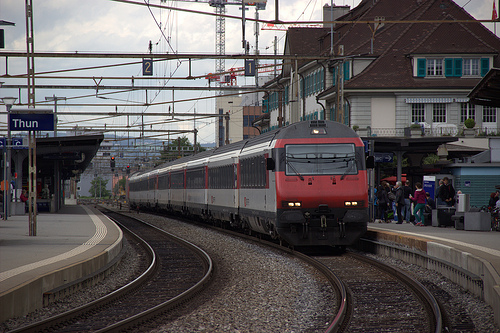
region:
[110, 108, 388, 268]
A train pulling into a station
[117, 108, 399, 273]
A train pulling into a station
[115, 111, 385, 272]
A train pulling into a station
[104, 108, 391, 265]
A train pulling into a station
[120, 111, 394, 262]
A train pulling into a station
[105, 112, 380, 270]
A train pulling into a station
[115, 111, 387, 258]
A train pulling into a station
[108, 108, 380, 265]
A train pulling into a station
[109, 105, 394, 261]
A train pulling into a station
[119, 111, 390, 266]
A train pulling into a station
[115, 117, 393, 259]
A train pulling into a station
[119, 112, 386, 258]
A train pulling into a station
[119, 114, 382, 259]
A train pulling into a station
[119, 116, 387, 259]
A train pulling into a station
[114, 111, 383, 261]
A train pulling into a station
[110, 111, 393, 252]
An incoming train at a train station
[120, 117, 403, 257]
An incoming train at a train station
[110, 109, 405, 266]
An incoming train at a train station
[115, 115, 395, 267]
An incoming train at a train station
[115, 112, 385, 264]
An incoming train at a train station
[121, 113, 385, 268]
An incoming train at a train station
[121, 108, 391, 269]
An incoming train at a train station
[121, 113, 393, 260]
An incoming train at a train station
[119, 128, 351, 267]
A tall red and grey train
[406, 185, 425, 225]
People outside a building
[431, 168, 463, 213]
People outside a building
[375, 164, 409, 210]
People outside a building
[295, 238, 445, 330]
A metalic train truck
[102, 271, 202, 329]
A metalic train truck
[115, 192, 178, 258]
A metalic train truck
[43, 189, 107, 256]
A grey tarmac walk way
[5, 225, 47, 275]
A grey tarmac walk way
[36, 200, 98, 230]
A grey tarmac walk way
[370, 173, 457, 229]
People waiting on a train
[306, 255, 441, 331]
Tracks for a train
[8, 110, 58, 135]
Blue sign at a station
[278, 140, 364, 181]
Wipers on the front of a train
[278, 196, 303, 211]
Lights on a train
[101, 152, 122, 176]
Traffic light on a post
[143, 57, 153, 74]
sign with the number 2 on it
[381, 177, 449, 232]
group of people waiting to board the train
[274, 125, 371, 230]
red and black train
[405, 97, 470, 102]
small striped window awning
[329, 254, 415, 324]
rusty old train tracks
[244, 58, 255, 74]
sign displaying the number 1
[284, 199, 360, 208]
headlights belonging to train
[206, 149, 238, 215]
first silver and red train car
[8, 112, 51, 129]
blue sign displaying the word "Thun"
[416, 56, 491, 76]
small window with blue shutters